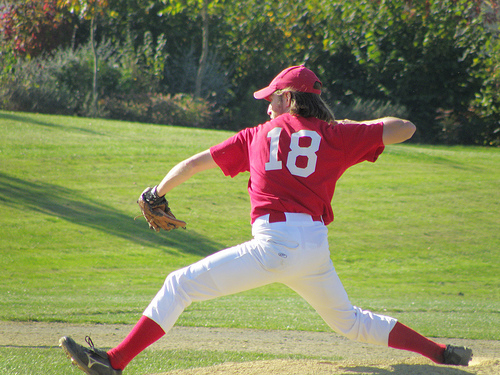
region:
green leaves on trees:
[192, 4, 487, 64]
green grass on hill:
[7, 111, 497, 321]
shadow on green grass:
[3, 173, 216, 259]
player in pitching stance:
[61, 63, 471, 372]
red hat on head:
[254, 65, 324, 100]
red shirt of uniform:
[213, 114, 385, 215]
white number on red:
[264, 128, 321, 177]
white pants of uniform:
[144, 211, 396, 346]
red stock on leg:
[109, 315, 166, 367]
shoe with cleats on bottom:
[59, 337, 120, 374]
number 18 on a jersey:
[260, 123, 327, 193]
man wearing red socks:
[370, 310, 445, 367]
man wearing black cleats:
[433, 328, 492, 365]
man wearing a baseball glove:
[134, 190, 191, 237]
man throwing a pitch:
[305, 95, 408, 162]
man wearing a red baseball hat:
[236, 67, 346, 114]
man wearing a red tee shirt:
[226, 107, 361, 199]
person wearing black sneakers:
[55, 322, 126, 374]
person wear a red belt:
[261, 205, 326, 232]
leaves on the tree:
[76, 8, 291, 84]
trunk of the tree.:
[189, 29, 209, 96]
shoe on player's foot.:
[443, 339, 474, 362]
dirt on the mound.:
[281, 361, 309, 373]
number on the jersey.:
[252, 128, 322, 170]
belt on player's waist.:
[260, 212, 288, 228]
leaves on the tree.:
[366, 15, 391, 40]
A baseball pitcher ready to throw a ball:
[55, 57, 480, 372]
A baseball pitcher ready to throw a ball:
[53, 58, 473, 370]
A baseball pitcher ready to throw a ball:
[56, 60, 484, 370]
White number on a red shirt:
[261, 116, 279, 183]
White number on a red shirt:
[286, 121, 320, 190]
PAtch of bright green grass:
[18, 273, 52, 308]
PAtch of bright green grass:
[53, 275, 106, 326]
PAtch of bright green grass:
[198, 301, 278, 323]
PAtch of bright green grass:
[448, 232, 499, 287]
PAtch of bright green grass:
[385, 228, 437, 293]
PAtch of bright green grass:
[332, 232, 368, 279]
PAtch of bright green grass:
[64, 121, 159, 148]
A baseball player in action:
[59, 66, 471, 373]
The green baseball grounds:
[0, 112, 498, 373]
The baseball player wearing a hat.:
[249, 66, 324, 118]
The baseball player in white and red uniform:
[59, 66, 471, 373]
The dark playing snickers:
[54, 334, 479, 374]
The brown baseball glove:
[139, 187, 186, 234]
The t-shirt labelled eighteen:
[211, 109, 383, 221]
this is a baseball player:
[32, 92, 402, 353]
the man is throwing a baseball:
[243, 88, 420, 285]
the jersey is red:
[191, 88, 380, 253]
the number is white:
[260, 114, 333, 191]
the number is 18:
[233, 101, 385, 198]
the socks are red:
[72, 310, 207, 370]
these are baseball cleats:
[47, 340, 150, 372]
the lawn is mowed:
[21, 146, 117, 267]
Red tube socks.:
[105, 322, 445, 373]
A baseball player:
[97, 75, 455, 366]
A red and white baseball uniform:
[120, 113, 460, 363]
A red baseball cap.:
[252, 65, 318, 90]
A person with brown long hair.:
[72, 64, 468, 365]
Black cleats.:
[44, 335, 481, 371]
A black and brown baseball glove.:
[142, 187, 183, 232]